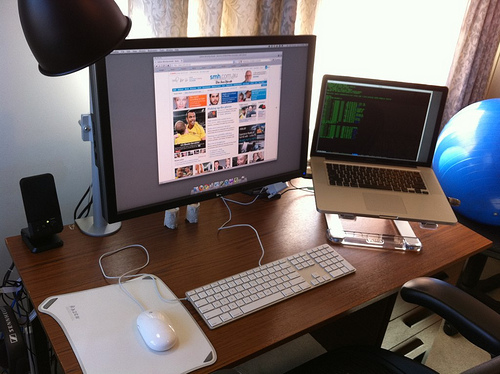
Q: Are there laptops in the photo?
A: Yes, there is a laptop.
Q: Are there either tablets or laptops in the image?
A: Yes, there is a laptop.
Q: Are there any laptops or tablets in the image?
A: Yes, there is a laptop.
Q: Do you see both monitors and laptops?
A: Yes, there are both a laptop and a monitor.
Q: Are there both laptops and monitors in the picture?
A: Yes, there are both a laptop and a monitor.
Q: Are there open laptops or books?
A: Yes, there is an open laptop.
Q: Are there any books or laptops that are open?
A: Yes, the laptop is open.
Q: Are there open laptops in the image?
A: Yes, there is an open laptop.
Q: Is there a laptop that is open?
A: Yes, there is a laptop that is open.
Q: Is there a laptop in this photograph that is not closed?
A: Yes, there is a open laptop.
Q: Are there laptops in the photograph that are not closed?
A: Yes, there is a open laptop.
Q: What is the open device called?
A: The device is a laptop.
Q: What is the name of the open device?
A: The device is a laptop.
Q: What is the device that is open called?
A: The device is a laptop.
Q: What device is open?
A: The device is a laptop.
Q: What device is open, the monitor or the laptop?
A: The laptop is open.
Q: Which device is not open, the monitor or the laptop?
A: The monitor is not open.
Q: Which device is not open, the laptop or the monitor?
A: The monitor is not open.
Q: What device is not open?
A: The device is a monitor.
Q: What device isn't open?
A: The device is a monitor.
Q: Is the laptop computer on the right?
A: Yes, the laptop computer is on the right of the image.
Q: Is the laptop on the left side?
A: No, the laptop is on the right of the image.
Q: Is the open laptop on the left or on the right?
A: The laptop is on the right of the image.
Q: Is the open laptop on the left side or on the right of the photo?
A: The laptop is on the right of the image.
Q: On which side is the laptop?
A: The laptop is on the right of the image.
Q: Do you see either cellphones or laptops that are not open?
A: No, there is a laptop but it is open.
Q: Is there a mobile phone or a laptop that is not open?
A: No, there is a laptop but it is open.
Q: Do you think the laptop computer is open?
A: Yes, the laptop computer is open.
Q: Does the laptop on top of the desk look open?
A: Yes, the laptop is open.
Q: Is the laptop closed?
A: No, the laptop is open.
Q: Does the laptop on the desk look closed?
A: No, the laptop is open.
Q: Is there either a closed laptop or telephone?
A: No, there is a laptop but it is open.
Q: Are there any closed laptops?
A: No, there is a laptop but it is open.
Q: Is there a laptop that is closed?
A: No, there is a laptop but it is open.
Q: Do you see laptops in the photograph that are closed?
A: No, there is a laptop but it is open.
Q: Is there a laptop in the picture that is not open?
A: No, there is a laptop but it is open.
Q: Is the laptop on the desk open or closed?
A: The laptop is open.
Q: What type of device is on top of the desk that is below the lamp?
A: The device is a laptop.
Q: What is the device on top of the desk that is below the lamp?
A: The device is a laptop.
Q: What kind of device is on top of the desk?
A: The device is a laptop.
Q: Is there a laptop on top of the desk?
A: Yes, there is a laptop on top of the desk.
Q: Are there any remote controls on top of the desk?
A: No, there is a laptop on top of the desk.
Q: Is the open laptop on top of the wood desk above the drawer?
A: Yes, the laptop is on top of the desk.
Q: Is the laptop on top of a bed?
A: No, the laptop is on top of the desk.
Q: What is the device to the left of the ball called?
A: The device is a laptop.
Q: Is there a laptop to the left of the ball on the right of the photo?
A: Yes, there is a laptop to the left of the ball.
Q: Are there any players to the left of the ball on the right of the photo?
A: No, there is a laptop to the left of the ball.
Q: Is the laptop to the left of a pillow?
A: No, the laptop is to the left of the ball.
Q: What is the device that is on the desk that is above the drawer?
A: The device is a laptop.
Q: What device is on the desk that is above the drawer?
A: The device is a laptop.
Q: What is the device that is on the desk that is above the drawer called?
A: The device is a laptop.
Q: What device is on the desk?
A: The device is a laptop.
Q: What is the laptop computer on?
A: The laptop computer is on the desk.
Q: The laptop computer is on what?
A: The laptop computer is on the desk.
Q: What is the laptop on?
A: The laptop computer is on the desk.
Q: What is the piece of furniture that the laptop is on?
A: The piece of furniture is a desk.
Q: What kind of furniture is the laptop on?
A: The laptop is on the desk.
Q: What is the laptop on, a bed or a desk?
A: The laptop is on a desk.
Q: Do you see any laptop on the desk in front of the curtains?
A: Yes, there is a laptop on the desk.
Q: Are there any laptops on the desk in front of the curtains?
A: Yes, there is a laptop on the desk.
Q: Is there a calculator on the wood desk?
A: No, there is a laptop on the desk.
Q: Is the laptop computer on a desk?
A: Yes, the laptop computer is on a desk.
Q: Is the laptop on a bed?
A: No, the laptop is on a desk.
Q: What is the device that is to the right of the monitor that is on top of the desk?
A: The device is a laptop.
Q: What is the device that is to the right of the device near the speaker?
A: The device is a laptop.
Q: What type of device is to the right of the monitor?
A: The device is a laptop.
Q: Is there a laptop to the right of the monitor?
A: Yes, there is a laptop to the right of the monitor.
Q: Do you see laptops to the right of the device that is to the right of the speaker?
A: Yes, there is a laptop to the right of the monitor.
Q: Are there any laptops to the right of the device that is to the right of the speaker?
A: Yes, there is a laptop to the right of the monitor.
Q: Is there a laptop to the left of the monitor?
A: No, the laptop is to the right of the monitor.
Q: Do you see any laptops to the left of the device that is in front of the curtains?
A: No, the laptop is to the right of the monitor.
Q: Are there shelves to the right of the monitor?
A: No, there is a laptop to the right of the monitor.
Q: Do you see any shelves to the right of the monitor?
A: No, there is a laptop to the right of the monitor.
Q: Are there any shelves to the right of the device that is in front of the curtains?
A: No, there is a laptop to the right of the monitor.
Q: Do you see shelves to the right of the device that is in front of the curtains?
A: No, there is a laptop to the right of the monitor.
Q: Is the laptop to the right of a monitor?
A: Yes, the laptop is to the right of a monitor.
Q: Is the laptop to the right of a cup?
A: No, the laptop is to the right of a monitor.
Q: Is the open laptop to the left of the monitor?
A: No, the laptop is to the right of the monitor.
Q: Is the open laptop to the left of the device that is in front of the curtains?
A: No, the laptop is to the right of the monitor.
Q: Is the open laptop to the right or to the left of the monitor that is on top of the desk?
A: The laptop is to the right of the monitor.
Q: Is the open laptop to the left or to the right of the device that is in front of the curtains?
A: The laptop is to the right of the monitor.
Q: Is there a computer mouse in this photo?
A: Yes, there is a computer mouse.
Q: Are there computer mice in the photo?
A: Yes, there is a computer mouse.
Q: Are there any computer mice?
A: Yes, there is a computer mouse.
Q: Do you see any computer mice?
A: Yes, there is a computer mouse.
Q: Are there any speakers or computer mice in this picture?
A: Yes, there is a computer mouse.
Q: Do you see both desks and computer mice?
A: Yes, there are both a computer mouse and a desk.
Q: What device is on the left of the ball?
A: The device is a computer mouse.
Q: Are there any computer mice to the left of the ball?
A: Yes, there is a computer mouse to the left of the ball.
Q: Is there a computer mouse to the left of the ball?
A: Yes, there is a computer mouse to the left of the ball.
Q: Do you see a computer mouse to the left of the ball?
A: Yes, there is a computer mouse to the left of the ball.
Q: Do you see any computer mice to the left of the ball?
A: Yes, there is a computer mouse to the left of the ball.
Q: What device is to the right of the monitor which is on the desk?
A: The device is a computer mouse.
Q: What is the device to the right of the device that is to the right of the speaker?
A: The device is a computer mouse.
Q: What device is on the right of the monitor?
A: The device is a computer mouse.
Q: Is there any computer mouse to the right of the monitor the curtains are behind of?
A: Yes, there is a computer mouse to the right of the monitor.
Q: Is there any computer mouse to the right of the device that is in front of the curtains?
A: Yes, there is a computer mouse to the right of the monitor.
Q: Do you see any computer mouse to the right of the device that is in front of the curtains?
A: Yes, there is a computer mouse to the right of the monitor.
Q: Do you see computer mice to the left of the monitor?
A: No, the computer mouse is to the right of the monitor.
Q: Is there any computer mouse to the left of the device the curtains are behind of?
A: No, the computer mouse is to the right of the monitor.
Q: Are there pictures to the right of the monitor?
A: No, there is a computer mouse to the right of the monitor.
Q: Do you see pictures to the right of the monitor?
A: No, there is a computer mouse to the right of the monitor.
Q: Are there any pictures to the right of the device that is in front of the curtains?
A: No, there is a computer mouse to the right of the monitor.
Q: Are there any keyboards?
A: Yes, there is a keyboard.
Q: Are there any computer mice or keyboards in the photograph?
A: Yes, there is a keyboard.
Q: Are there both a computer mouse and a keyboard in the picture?
A: Yes, there are both a keyboard and a computer mouse.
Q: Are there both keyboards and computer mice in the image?
A: Yes, there are both a keyboard and a computer mouse.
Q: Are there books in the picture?
A: No, there are no books.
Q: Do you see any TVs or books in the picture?
A: No, there are no books or tvs.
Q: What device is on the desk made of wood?
A: The device is a keyboard.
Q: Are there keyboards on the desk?
A: Yes, there is a keyboard on the desk.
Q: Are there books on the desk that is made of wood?
A: No, there is a keyboard on the desk.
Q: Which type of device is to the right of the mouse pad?
A: The device is a keyboard.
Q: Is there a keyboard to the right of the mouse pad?
A: Yes, there is a keyboard to the right of the mouse pad.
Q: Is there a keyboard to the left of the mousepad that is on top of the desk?
A: No, the keyboard is to the right of the mouse pad.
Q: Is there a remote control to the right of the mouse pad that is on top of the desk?
A: No, there is a keyboard to the right of the mouse pad.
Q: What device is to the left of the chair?
A: The device is a keyboard.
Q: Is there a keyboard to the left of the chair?
A: Yes, there is a keyboard to the left of the chair.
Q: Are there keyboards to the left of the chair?
A: Yes, there is a keyboard to the left of the chair.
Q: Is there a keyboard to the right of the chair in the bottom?
A: No, the keyboard is to the left of the chair.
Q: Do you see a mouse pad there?
A: Yes, there is a mouse pad.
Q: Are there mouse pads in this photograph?
A: Yes, there is a mouse pad.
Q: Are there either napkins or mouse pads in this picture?
A: Yes, there is a mouse pad.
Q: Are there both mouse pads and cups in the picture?
A: No, there is a mouse pad but no cups.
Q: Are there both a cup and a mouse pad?
A: No, there is a mouse pad but no cups.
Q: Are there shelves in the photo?
A: No, there are no shelves.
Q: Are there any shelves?
A: No, there are no shelves.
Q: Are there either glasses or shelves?
A: No, there are no shelves or glasses.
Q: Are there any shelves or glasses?
A: No, there are no shelves or glasses.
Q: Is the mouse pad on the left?
A: Yes, the mouse pad is on the left of the image.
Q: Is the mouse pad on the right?
A: No, the mouse pad is on the left of the image.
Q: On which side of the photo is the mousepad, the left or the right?
A: The mousepad is on the left of the image.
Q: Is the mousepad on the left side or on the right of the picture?
A: The mousepad is on the left of the image.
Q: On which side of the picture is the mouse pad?
A: The mouse pad is on the left of the image.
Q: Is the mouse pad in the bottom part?
A: Yes, the mouse pad is in the bottom of the image.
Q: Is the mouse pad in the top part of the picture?
A: No, the mouse pad is in the bottom of the image.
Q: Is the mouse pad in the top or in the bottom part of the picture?
A: The mouse pad is in the bottom of the image.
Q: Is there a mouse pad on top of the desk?
A: Yes, there is a mouse pad on top of the desk.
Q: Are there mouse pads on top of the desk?
A: Yes, there is a mouse pad on top of the desk.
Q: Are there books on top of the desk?
A: No, there is a mouse pad on top of the desk.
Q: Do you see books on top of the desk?
A: No, there is a mouse pad on top of the desk.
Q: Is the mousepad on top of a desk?
A: Yes, the mousepad is on top of a desk.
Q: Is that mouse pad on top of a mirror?
A: No, the mouse pad is on top of a desk.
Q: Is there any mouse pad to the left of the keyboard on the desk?
A: Yes, there is a mouse pad to the left of the keyboard.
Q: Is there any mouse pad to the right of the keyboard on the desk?
A: No, the mouse pad is to the left of the keyboard.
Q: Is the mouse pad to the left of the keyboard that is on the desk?
A: Yes, the mouse pad is to the left of the keyboard.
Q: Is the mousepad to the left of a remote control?
A: No, the mousepad is to the left of the keyboard.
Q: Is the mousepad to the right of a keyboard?
A: No, the mousepad is to the left of a keyboard.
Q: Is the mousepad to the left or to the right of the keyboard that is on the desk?
A: The mousepad is to the left of the keyboard.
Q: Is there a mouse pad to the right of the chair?
A: No, the mouse pad is to the left of the chair.